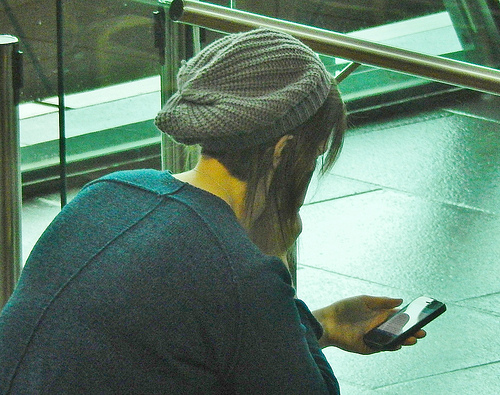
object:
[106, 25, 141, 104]
glass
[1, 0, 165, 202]
window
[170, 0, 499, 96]
railing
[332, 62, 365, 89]
tilted pole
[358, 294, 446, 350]
cell phone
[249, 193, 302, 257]
hand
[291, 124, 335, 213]
face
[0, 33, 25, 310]
post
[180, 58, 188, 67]
yarn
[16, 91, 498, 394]
tile floor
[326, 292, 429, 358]
hand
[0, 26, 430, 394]
girl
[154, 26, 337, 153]
hat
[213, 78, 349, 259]
hair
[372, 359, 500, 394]
tile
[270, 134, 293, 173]
man's ear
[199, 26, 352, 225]
head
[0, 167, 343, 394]
shirt